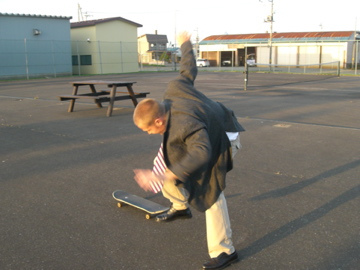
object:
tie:
[150, 140, 169, 194]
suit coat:
[161, 39, 246, 212]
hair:
[132, 99, 167, 126]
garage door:
[321, 44, 348, 69]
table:
[59, 79, 151, 118]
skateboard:
[112, 189, 172, 221]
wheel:
[117, 202, 121, 209]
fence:
[0, 37, 359, 80]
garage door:
[297, 42, 322, 68]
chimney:
[154, 29, 157, 35]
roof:
[138, 33, 169, 45]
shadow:
[234, 158, 359, 264]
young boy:
[132, 31, 246, 269]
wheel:
[145, 213, 151, 221]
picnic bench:
[59, 95, 115, 117]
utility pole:
[264, 0, 275, 72]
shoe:
[154, 206, 194, 222]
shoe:
[202, 248, 239, 270]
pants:
[161, 133, 243, 259]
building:
[198, 31, 359, 73]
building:
[1, 12, 74, 78]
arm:
[178, 33, 199, 88]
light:
[32, 27, 39, 37]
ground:
[0, 71, 360, 269]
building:
[138, 30, 178, 69]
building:
[70, 16, 143, 75]